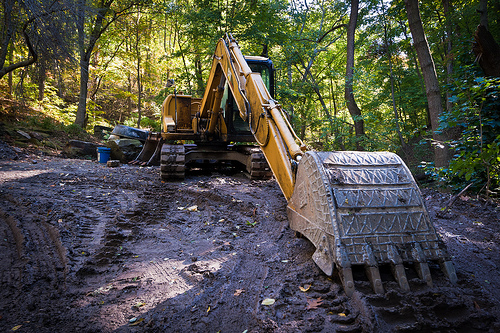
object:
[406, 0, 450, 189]
tree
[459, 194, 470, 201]
leaf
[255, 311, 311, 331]
ground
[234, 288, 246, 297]
leaf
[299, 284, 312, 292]
leaf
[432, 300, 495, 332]
ground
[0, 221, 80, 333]
ground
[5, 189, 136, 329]
dirt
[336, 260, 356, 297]
prongs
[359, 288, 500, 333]
mud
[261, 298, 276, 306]
leaf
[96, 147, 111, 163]
container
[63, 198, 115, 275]
tracks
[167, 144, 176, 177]
mud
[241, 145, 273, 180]
wheel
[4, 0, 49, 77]
trees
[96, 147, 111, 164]
buck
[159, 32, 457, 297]
backhoe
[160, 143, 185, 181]
tracks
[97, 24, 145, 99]
trees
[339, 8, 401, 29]
sky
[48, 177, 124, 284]
mud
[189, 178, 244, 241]
ground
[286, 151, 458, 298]
bucket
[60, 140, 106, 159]
rocks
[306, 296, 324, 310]
leaf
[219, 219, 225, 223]
leaf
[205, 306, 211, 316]
leaf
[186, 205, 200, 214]
leaf